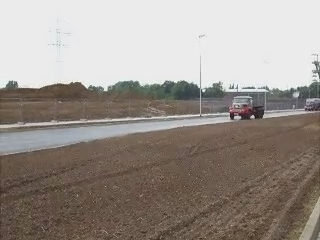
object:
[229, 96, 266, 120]
truck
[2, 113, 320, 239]
dirt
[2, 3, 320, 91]
sky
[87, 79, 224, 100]
trees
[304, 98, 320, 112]
truck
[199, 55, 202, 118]
pole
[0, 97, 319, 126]
fence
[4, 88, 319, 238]
ground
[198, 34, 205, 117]
light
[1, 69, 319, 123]
background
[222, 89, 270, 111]
house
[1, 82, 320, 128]
dirt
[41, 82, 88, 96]
pile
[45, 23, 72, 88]
tower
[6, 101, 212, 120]
patch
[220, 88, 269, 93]
top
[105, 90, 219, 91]
line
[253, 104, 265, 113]
bed